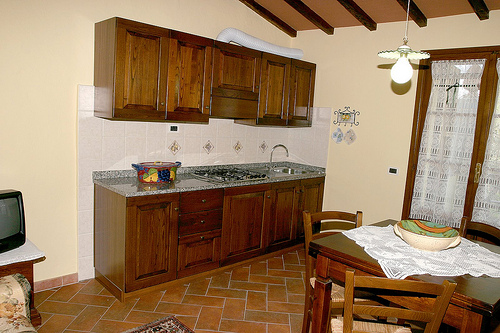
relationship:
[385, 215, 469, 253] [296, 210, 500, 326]
bowl on table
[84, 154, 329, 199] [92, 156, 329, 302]
countertop on cabinets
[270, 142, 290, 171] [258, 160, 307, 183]
faucet on sink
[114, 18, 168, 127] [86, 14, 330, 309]
door on cabinet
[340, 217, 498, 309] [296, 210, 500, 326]
cloth on table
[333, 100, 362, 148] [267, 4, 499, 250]
items on wall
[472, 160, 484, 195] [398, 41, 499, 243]
knob on door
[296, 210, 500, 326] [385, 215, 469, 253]
table has bowl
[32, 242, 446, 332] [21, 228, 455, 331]
floor has tile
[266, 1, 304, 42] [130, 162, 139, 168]
rafters with handle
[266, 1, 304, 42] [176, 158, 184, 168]
rafters with handle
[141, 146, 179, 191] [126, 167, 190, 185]
pot with fruit decorations